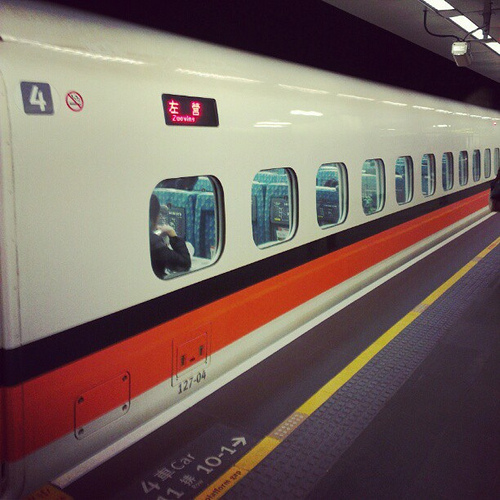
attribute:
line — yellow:
[137, 227, 498, 498]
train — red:
[4, 2, 496, 438]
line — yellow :
[272, 287, 466, 390]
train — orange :
[281, 57, 488, 222]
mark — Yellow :
[311, 330, 438, 387]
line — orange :
[32, 344, 93, 352]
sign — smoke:
[61, 87, 88, 115]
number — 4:
[16, 76, 55, 116]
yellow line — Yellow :
[198, 341, 453, 472]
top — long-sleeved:
[149, 232, 188, 275]